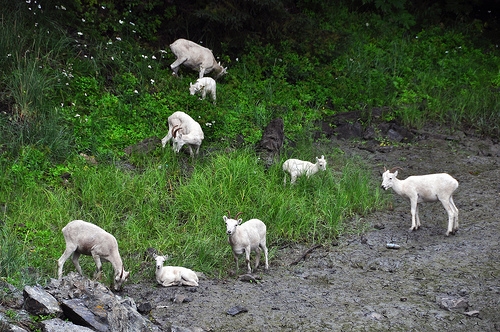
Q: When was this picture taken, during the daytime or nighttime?
A: Daytime.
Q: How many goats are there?
A: Eight.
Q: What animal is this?
A: Goat.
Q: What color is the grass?
A: Green.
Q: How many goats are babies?
A: Three.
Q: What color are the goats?
A: White.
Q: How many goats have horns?
A: Five.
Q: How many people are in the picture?
A: None.